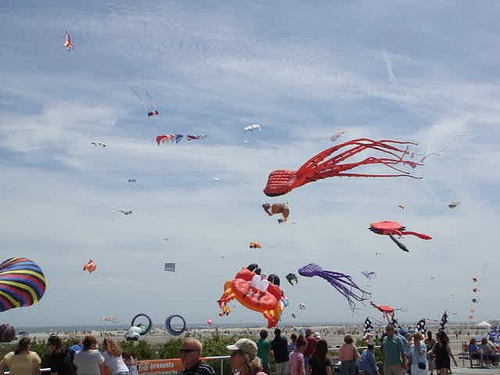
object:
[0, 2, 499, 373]
daytime scene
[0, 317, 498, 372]
people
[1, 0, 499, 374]
weather looks windy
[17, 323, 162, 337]
hills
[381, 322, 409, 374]
man walking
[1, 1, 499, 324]
sky looks beautiful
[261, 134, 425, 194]
crab shaped kite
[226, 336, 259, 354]
baseball cap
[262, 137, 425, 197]
red kite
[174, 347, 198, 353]
sunglasses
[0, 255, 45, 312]
multicolored stripes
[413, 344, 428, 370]
black purse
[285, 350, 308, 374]
pink shirt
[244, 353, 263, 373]
long hair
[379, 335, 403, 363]
green shirt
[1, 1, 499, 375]
outdoor scene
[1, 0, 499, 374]
photo is clear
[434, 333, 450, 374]
dress is black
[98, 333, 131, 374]
woman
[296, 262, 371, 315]
purple kite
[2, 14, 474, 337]
kites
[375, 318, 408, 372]
man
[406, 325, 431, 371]
wife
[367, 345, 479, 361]
road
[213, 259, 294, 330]
kite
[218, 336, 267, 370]
woman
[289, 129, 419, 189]
tails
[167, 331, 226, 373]
man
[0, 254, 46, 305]
kite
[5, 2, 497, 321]
sky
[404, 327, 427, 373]
woman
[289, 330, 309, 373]
woman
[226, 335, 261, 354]
hat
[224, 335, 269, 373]
lady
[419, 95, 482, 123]
no objects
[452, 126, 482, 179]
no objects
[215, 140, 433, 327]
objects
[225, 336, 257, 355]
lid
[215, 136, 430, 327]
balloons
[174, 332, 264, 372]
friends